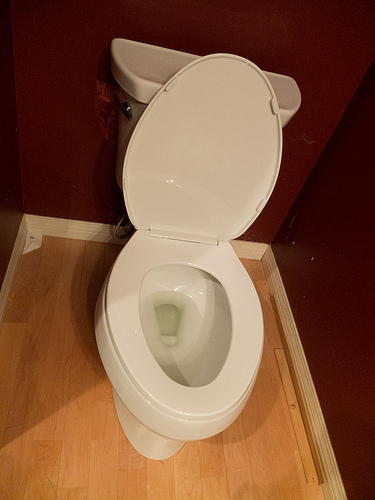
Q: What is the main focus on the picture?
A: A toilet.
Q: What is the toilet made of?
A: Porcelain.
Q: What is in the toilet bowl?
A: Water.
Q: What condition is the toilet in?
A: Clean.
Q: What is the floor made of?
A: Wood.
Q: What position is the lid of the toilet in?
A: Open.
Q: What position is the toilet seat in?
A: Closed.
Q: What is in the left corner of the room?
A: A small piece of paper.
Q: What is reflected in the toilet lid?
A: The toilet seat.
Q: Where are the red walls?
A: In the bathroom surrounding the toilet.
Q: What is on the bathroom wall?
A: Paint.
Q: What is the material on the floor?
A: Wood floor.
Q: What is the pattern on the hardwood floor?
A: Light color.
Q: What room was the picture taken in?
A: Bathroom.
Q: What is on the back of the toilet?
A: Back rest.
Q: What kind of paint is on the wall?
A: Red.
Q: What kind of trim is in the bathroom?
A: White.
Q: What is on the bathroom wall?
A: Dark red.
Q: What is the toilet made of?
A: White porcelain.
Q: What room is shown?
A: Bathroom.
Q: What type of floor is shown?
A: Hardwood.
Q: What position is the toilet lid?
A: Raised.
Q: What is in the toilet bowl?
A: Water.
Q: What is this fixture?
A: Toilet.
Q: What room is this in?
A: Restroom.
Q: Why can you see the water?
A: The lid is up.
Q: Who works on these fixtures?
A: Plumbers.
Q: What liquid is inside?
A: Water.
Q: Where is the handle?
A: On the tank.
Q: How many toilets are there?
A: 1.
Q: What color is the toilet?
A: White.